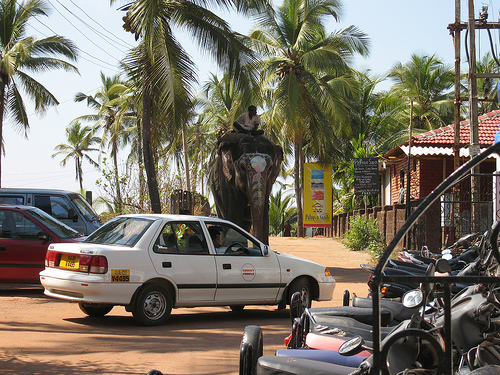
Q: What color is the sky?
A: Light Blue.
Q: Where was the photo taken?
A: Parking lot.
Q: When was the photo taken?
A: Daytime.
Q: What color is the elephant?
A: Gray.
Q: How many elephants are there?
A: One.